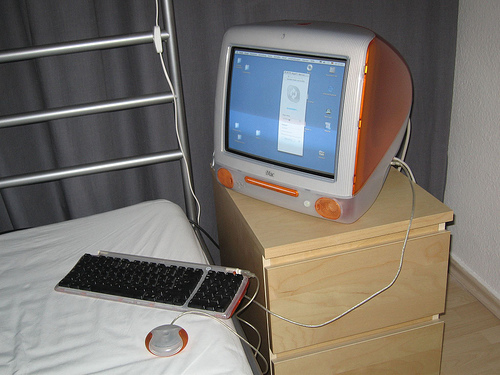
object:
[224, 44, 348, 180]
monitor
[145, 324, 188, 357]
mouse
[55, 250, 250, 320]
keyboard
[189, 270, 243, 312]
pad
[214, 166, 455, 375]
nightstand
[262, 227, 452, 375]
drawers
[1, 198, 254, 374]
mattress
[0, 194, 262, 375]
bed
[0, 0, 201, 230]
headboard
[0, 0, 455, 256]
curtains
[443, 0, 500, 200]
wall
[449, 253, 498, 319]
baseboard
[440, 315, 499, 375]
floor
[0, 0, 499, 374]
room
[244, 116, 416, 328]
cord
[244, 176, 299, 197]
speakers